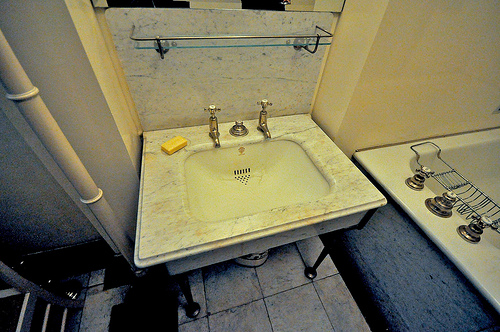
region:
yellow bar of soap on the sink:
[158, 131, 189, 156]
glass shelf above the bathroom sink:
[126, 25, 336, 150]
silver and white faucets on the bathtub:
[406, 161, 495, 251]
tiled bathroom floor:
[202, 280, 344, 330]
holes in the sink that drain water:
[232, 165, 252, 188]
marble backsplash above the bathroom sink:
[94, 6, 337, 131]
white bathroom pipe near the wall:
[0, 21, 139, 277]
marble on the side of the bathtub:
[368, 248, 432, 315]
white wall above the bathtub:
[389, 0, 488, 182]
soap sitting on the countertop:
[156, 127, 191, 156]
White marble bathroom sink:
[133, 103, 390, 280]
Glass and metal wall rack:
[128, 23, 336, 61]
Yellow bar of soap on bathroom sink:
[158, 133, 190, 158]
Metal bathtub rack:
[408, 138, 499, 236]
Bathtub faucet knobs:
[403, 165, 496, 245]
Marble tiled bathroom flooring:
[75, 230, 370, 329]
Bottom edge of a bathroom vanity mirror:
[88, 0, 349, 12]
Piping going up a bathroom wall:
[0, 33, 133, 262]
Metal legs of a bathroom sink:
[177, 225, 341, 320]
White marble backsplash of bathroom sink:
[103, 6, 335, 133]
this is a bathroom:
[3, 5, 498, 330]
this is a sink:
[117, 85, 399, 296]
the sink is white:
[172, 114, 330, 219]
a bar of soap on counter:
[155, 113, 200, 172]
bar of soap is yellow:
[150, 120, 197, 170]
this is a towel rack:
[98, 2, 355, 109]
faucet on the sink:
[173, 85, 293, 150]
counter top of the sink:
[116, 101, 208, 261]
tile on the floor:
[205, 268, 360, 330]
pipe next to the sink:
[0, 7, 152, 267]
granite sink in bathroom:
[106, 37, 407, 303]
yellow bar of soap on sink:
[158, 132, 192, 157]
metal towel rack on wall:
[129, 16, 343, 57]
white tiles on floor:
[170, 231, 402, 329]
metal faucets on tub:
[393, 163, 499, 237]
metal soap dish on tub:
[412, 133, 499, 237]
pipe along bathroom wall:
[4, 70, 152, 285]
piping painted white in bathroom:
[5, 63, 147, 279]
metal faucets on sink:
[197, 95, 287, 152]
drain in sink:
[230, 161, 269, 188]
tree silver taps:
[394, 148, 497, 250]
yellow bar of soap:
[159, 130, 196, 157]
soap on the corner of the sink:
[156, 125, 193, 162]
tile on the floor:
[68, 243, 384, 330]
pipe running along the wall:
[0, 24, 152, 281]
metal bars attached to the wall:
[126, 18, 331, 65]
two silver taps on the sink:
[201, 96, 291, 151]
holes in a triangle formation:
[229, 173, 251, 185]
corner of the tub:
[347, 121, 411, 289]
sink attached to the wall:
[128, 91, 390, 288]